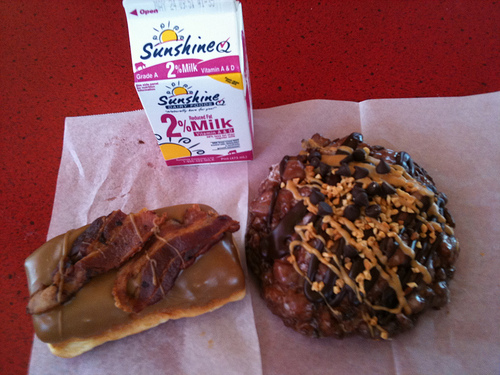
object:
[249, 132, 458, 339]
donut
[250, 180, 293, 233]
chocolate frosting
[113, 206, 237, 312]
bacon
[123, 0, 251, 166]
milk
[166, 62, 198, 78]
2% milk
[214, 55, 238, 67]
purple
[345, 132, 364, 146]
chocolate chips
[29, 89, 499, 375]
paper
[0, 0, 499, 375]
table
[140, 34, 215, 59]
sunshine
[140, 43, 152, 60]
blue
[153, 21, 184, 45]
suns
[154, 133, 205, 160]
sunshine symbol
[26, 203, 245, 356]
food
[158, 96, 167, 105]
letters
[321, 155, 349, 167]
frosting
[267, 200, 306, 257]
chocolate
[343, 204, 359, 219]
topping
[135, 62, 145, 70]
carton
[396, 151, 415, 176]
icing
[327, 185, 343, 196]
nuts